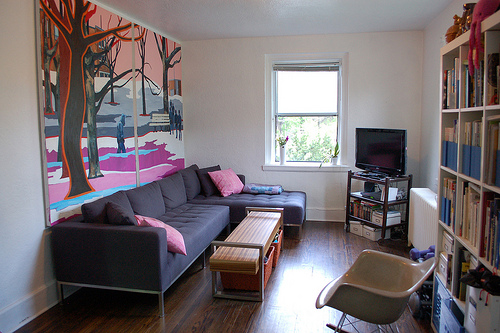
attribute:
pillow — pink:
[208, 166, 245, 197]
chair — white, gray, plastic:
[314, 240, 441, 325]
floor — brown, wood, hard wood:
[15, 221, 435, 332]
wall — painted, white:
[182, 35, 422, 223]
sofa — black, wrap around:
[50, 164, 308, 332]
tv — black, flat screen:
[356, 127, 406, 174]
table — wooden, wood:
[211, 206, 285, 304]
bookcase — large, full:
[432, 11, 498, 332]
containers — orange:
[220, 246, 275, 292]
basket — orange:
[217, 247, 274, 291]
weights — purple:
[408, 246, 434, 261]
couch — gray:
[50, 164, 308, 318]